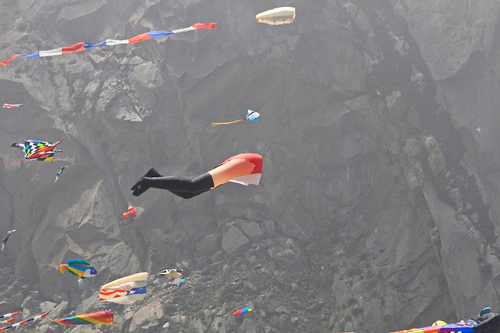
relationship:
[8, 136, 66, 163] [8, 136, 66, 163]
kite on kite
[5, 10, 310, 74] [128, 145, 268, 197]
kites flying kites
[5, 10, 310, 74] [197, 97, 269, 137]
kites flying kites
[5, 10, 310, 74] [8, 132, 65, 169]
kites flying kites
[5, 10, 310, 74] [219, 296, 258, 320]
kites flying kites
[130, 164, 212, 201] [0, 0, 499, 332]
leggings in mountain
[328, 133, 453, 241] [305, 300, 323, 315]
wall with rock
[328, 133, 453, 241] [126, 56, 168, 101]
wall with rock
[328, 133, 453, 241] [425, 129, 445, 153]
wall with rock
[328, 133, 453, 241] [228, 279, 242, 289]
wall with rock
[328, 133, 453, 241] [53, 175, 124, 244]
wall with rock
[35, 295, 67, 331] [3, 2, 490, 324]
snow on a mountain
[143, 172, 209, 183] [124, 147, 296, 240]
light on a leg